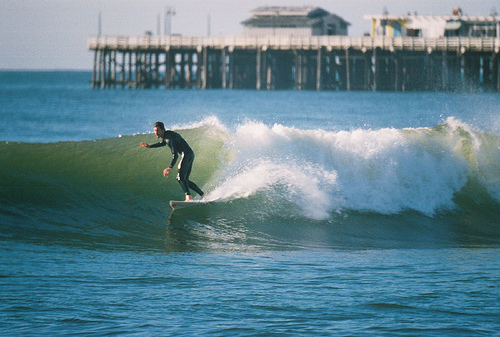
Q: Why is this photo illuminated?
A: Sunlight.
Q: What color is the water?
A: Blue.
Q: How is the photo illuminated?
A: Daylight.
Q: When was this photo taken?
A: During the day.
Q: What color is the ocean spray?
A: White.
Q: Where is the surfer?
A: In the water.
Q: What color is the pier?
A: Gray.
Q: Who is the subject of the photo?
A: The surfer.